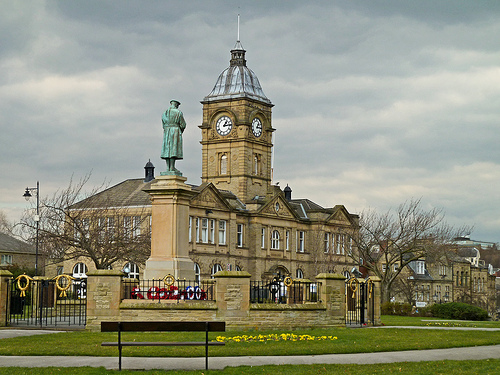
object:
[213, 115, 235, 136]
clock face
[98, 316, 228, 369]
bench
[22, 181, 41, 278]
street lamp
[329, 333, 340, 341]
flowers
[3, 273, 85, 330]
gate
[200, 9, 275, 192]
tower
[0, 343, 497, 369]
path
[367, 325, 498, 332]
path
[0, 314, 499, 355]
grass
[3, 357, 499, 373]
grass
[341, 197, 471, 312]
bare tree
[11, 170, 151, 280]
bare tree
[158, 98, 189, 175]
statue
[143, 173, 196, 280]
pedestal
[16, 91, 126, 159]
sky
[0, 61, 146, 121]
clouds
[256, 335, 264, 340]
yellow flowers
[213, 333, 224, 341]
plants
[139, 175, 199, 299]
tower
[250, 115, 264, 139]
clock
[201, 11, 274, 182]
clocktower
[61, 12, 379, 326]
building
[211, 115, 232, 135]
clock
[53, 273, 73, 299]
decoration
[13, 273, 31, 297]
decoration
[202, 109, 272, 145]
two clocks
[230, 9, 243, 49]
pole